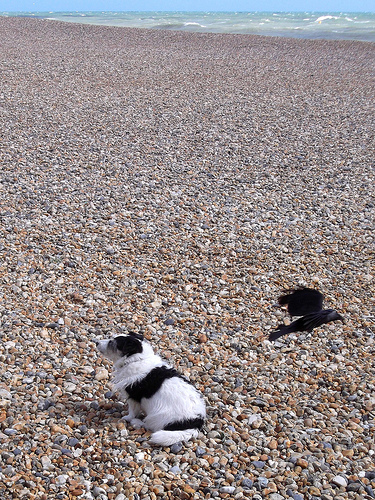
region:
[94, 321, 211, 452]
a dog sitting on gravel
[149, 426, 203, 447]
the tail of a dog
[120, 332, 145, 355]
the ear of a dog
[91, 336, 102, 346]
the nose of a dog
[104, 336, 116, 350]
the eye of a dog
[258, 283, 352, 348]
a flying black bird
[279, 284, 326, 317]
the wing of a bird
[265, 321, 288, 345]
the tail of a bird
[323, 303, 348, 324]
the head of a bird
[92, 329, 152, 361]
the head of a dog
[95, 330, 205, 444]
the dog is sitting on the rocks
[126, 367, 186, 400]
a black stripe on the dog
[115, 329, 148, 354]
the dog's ears are black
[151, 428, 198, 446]
the dog's tail is white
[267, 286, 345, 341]
the black crow is flying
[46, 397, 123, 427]
a shadow on the rocks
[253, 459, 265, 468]
small gray rock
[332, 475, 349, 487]
a white rock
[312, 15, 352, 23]
a white cap wave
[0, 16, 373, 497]
rocks on the shoreline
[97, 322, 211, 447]
black dog on rocks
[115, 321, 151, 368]
dog has black ears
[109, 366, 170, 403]
black stripe on back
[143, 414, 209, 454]
black stripe near tail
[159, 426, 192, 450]
dog has white tail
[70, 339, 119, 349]
dog has grey nose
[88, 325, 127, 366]
dog has white face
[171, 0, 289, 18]
blue and clear sky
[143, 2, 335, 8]
no clouds in sky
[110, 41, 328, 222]
rocks are many colors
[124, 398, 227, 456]
the dog is sitting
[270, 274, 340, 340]
the bird is flying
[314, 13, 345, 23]
the wave is white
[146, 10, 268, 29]
the water has waves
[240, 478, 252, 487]
the rock is gray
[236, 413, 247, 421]
the rock is brown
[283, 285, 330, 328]
the bird is black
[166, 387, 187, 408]
the dog is white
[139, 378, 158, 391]
the dog is black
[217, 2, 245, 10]
the sky is torquiose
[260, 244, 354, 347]
this is a bird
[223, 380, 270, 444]
these are small stones on the ground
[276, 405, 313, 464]
these are small stones on the ground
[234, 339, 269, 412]
these are small stones on the ground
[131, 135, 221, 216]
these are small stones on the ground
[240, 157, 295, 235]
these are small stones on the ground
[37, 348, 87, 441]
these are small stones on the ground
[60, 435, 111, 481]
these are small stones on the ground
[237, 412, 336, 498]
these are small stones on the ground